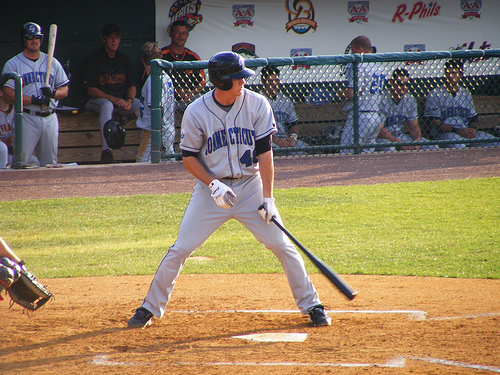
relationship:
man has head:
[127, 48, 332, 328] [207, 51, 249, 97]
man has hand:
[127, 48, 332, 328] [205, 177, 237, 209]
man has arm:
[127, 48, 332, 328] [180, 100, 235, 210]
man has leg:
[127, 48, 332, 328] [244, 176, 331, 327]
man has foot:
[127, 48, 332, 328] [302, 304, 330, 327]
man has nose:
[127, 48, 332, 328] [238, 77, 246, 86]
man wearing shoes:
[127, 48, 332, 328] [126, 306, 332, 326]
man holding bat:
[127, 48, 332, 328] [259, 201, 358, 301]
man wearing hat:
[127, 48, 332, 328] [209, 50, 259, 92]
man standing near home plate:
[127, 48, 332, 328] [228, 330, 311, 346]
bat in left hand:
[259, 201, 358, 301] [263, 197, 279, 224]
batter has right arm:
[127, 48, 332, 328] [180, 100, 235, 210]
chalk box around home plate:
[91, 304, 429, 368] [228, 330, 311, 346]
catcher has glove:
[0, 235, 20, 291] [5, 267, 51, 309]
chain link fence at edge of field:
[149, 49, 500, 162] [0, 145, 499, 176]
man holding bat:
[1, 20, 70, 167] [44, 23, 58, 86]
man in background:
[1, 20, 70, 167] [0, 1, 499, 169]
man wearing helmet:
[127, 48, 332, 328] [209, 50, 259, 92]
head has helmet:
[207, 51, 249, 97] [209, 50, 259, 92]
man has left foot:
[127, 48, 332, 328] [127, 302, 154, 329]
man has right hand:
[127, 48, 332, 328] [205, 177, 237, 209]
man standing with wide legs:
[127, 48, 332, 328] [128, 186, 329, 327]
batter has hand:
[127, 48, 332, 328] [205, 177, 237, 209]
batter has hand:
[127, 48, 332, 328] [263, 197, 279, 224]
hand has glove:
[205, 177, 237, 209] [211, 177, 237, 208]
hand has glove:
[263, 197, 279, 224] [258, 198, 280, 227]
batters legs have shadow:
[128, 186, 329, 327] [1, 323, 316, 369]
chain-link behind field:
[149, 49, 500, 162] [15, 145, 499, 373]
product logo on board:
[230, 1, 257, 30] [155, 1, 500, 85]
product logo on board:
[283, 1, 318, 35] [155, 1, 500, 85]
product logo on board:
[345, 1, 371, 24] [155, 1, 500, 85]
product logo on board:
[458, 0, 484, 19] [155, 1, 500, 85]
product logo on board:
[390, 1, 443, 25] [155, 1, 500, 85]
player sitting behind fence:
[425, 60, 494, 145] [0, 1, 499, 169]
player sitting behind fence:
[375, 67, 439, 149] [0, 1, 499, 169]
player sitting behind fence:
[258, 64, 309, 149] [0, 1, 499, 169]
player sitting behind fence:
[84, 24, 138, 166] [0, 1, 499, 169]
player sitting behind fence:
[141, 21, 205, 97] [0, 1, 499, 169]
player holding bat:
[1, 20, 70, 167] [44, 23, 58, 86]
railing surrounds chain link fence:
[150, 47, 498, 160] [149, 49, 500, 162]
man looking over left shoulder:
[127, 48, 332, 328] [242, 87, 278, 129]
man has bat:
[1, 20, 70, 167] [44, 23, 58, 86]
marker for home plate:
[91, 304, 429, 368] [228, 330, 311, 346]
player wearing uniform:
[425, 60, 494, 145] [428, 80, 499, 147]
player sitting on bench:
[84, 24, 138, 166] [0, 95, 499, 168]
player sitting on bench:
[141, 21, 205, 97] [0, 95, 499, 168]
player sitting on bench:
[258, 64, 309, 149] [0, 95, 499, 168]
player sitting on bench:
[375, 67, 439, 149] [0, 95, 499, 168]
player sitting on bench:
[425, 60, 494, 145] [0, 95, 499, 168]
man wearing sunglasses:
[1, 20, 70, 167] [24, 33, 48, 41]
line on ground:
[426, 312, 500, 324] [15, 145, 499, 373]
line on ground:
[417, 352, 499, 374] [15, 145, 499, 373]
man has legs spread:
[127, 48, 332, 328] [128, 186, 329, 327]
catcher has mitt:
[0, 235, 20, 291] [5, 267, 51, 309]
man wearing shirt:
[127, 48, 332, 328] [176, 90, 277, 174]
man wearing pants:
[127, 48, 332, 328] [141, 176, 322, 320]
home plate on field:
[228, 330, 311, 346] [15, 145, 499, 373]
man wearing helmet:
[1, 20, 70, 167] [21, 21, 42, 39]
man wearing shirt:
[1, 20, 70, 167] [1, 48, 70, 111]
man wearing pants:
[1, 20, 70, 167] [10, 108, 58, 168]